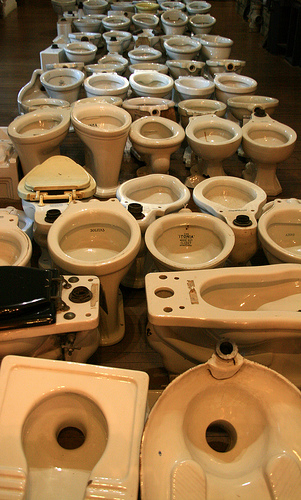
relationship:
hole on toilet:
[178, 299, 185, 313] [137, 258, 298, 328]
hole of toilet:
[178, 299, 185, 313] [137, 258, 298, 328]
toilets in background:
[48, 13, 243, 75] [3, 1, 300, 102]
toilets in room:
[48, 13, 243, 75] [2, 2, 299, 242]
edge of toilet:
[141, 269, 156, 285] [137, 258, 298, 328]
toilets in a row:
[48, 13, 243, 75] [13, 99, 291, 168]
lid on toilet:
[23, 149, 92, 193] [14, 153, 111, 219]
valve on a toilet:
[160, 308, 207, 326] [137, 258, 298, 328]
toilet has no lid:
[137, 258, 298, 328] [204, 277, 299, 309]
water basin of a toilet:
[15, 69, 42, 101] [137, 258, 298, 328]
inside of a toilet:
[248, 290, 261, 307] [137, 258, 298, 328]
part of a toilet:
[189, 318, 225, 328] [137, 258, 298, 328]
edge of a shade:
[282, 50, 300, 64] [263, 1, 300, 69]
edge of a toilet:
[141, 269, 156, 285] [137, 258, 298, 328]